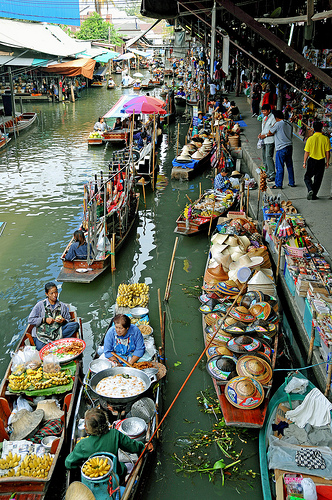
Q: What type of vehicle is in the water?
A: Boat.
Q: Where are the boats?
A: In the water.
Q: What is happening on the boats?
A: People are selling things.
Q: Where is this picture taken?
A: A canal.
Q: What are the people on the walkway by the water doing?
A: Shopping.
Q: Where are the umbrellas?
A: Above the boats.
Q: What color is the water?
A: Green.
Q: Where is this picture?
A: A city.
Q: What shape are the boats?
A: Oval.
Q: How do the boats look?
A: Long.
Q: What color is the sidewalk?
A: Gray.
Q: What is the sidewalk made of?
A: Stone.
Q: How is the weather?
A: Warm.